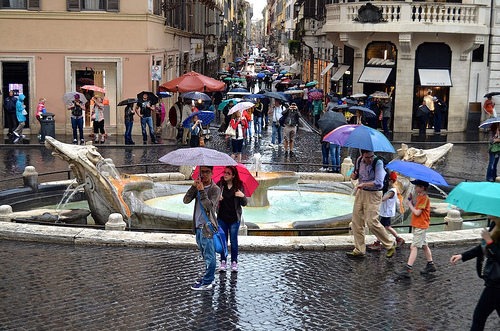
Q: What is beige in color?
A: The building.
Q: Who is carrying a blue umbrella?
A: Young boy.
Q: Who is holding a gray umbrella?
A: A man.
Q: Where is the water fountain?
A: Behind the people.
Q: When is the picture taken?
A: On a rainy day.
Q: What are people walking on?
A: Cobblestone.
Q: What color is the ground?
A: Dark brown.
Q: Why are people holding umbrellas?
A: It is raining.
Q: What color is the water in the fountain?
A: Light blue.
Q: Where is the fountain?
A: In the middle of the courtyard.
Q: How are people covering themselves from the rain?
A: With umbrellas.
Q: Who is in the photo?
A: Men, women, and children.